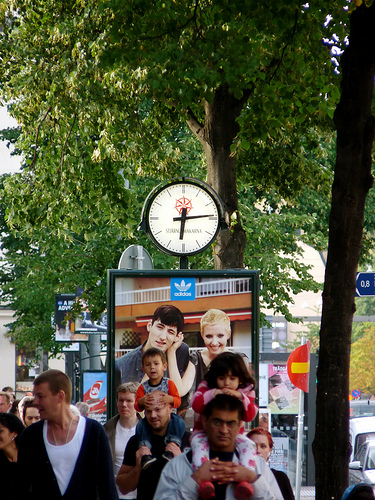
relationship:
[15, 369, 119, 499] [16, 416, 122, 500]
man wearing black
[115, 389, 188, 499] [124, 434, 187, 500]
man wearing black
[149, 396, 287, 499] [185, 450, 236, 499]
man wearing black